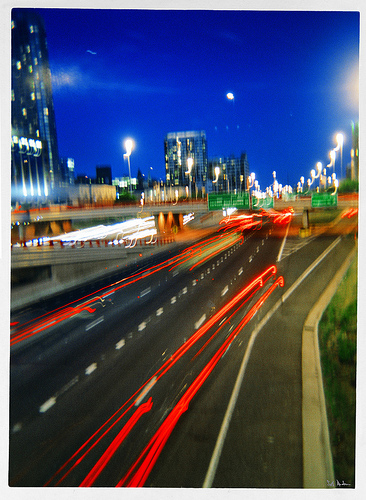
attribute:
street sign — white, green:
[204, 188, 250, 208]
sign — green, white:
[208, 195, 249, 209]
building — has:
[165, 133, 211, 194]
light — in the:
[116, 136, 141, 161]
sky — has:
[39, 9, 359, 178]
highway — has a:
[9, 195, 354, 487]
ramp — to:
[10, 233, 180, 310]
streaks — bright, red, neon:
[43, 264, 285, 487]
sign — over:
[202, 188, 251, 209]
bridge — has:
[18, 202, 359, 242]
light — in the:
[116, 135, 137, 160]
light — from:
[117, 275, 285, 491]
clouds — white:
[50, 71, 171, 96]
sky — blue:
[8, 12, 357, 207]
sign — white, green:
[251, 191, 275, 209]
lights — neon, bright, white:
[26, 214, 164, 247]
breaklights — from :
[152, 329, 224, 426]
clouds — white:
[73, 73, 149, 96]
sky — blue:
[249, 31, 299, 66]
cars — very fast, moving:
[15, 206, 355, 477]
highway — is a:
[17, 214, 360, 492]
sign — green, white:
[307, 187, 339, 212]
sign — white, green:
[204, 188, 254, 212]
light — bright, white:
[335, 134, 345, 149]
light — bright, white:
[328, 147, 336, 162]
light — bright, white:
[315, 162, 321, 171]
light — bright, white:
[308, 167, 315, 177]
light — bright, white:
[122, 139, 135, 153]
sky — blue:
[53, 11, 349, 116]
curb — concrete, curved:
[299, 242, 357, 487]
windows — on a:
[12, 57, 44, 132]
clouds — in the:
[53, 69, 78, 91]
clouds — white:
[48, 61, 109, 106]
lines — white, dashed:
[47, 284, 156, 415]